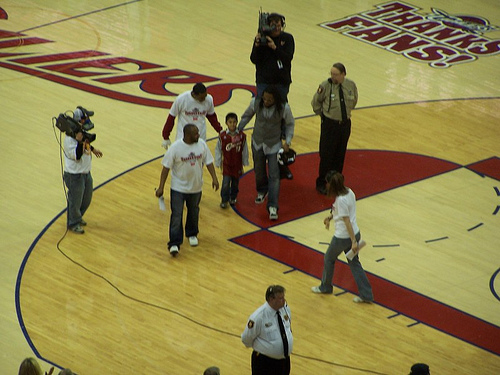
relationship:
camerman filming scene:
[249, 6, 299, 180] [146, 6, 388, 306]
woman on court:
[310, 168, 377, 305] [6, 4, 496, 367]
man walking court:
[155, 121, 221, 256] [6, 4, 496, 367]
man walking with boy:
[159, 82, 226, 152] [212, 113, 251, 210]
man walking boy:
[159, 82, 226, 152] [212, 113, 251, 210]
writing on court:
[316, 0, 499, 72] [6, 4, 496, 367]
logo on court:
[0, 6, 259, 112] [6, 4, 496, 367]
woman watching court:
[11, 353, 61, 375] [6, 4, 496, 367]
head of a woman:
[17, 357, 43, 375] [11, 353, 61, 375]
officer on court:
[311, 61, 359, 195] [6, 4, 496, 367]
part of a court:
[95, 17, 231, 56] [6, 4, 496, 367]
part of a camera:
[260, 19, 268, 32] [256, 8, 276, 46]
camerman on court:
[249, 6, 299, 180] [6, 4, 496, 367]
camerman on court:
[50, 104, 105, 238] [6, 4, 496, 367]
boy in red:
[212, 113, 251, 210] [221, 132, 244, 175]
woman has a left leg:
[310, 168, 377, 305] [311, 243, 342, 297]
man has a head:
[155, 121, 221, 256] [183, 121, 202, 145]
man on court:
[155, 121, 221, 256] [6, 4, 496, 367]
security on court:
[239, 283, 299, 375] [6, 4, 496, 367]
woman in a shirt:
[310, 168, 377, 305] [330, 188, 363, 240]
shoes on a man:
[160, 233, 200, 256] [155, 121, 221, 256]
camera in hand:
[256, 8, 276, 46] [264, 35, 279, 53]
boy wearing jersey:
[212, 113, 251, 210] [221, 132, 244, 175]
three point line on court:
[13, 7, 116, 50] [6, 4, 496, 367]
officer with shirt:
[311, 61, 359, 195] [310, 78, 359, 122]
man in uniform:
[311, 61, 359, 195] [313, 79, 355, 182]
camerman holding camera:
[249, 6, 299, 180] [256, 8, 276, 46]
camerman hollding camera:
[50, 104, 105, 238] [54, 111, 97, 145]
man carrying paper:
[155, 121, 221, 256] [153, 185, 167, 212]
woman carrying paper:
[310, 168, 377, 305] [343, 241, 368, 263]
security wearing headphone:
[239, 283, 299, 375] [268, 286, 290, 311]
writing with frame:
[316, 0, 499, 72] [344, 31, 364, 39]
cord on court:
[53, 216, 387, 374] [6, 4, 496, 367]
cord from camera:
[53, 216, 387, 374] [54, 111, 97, 145]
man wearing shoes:
[155, 121, 221, 256] [160, 233, 200, 256]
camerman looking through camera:
[249, 6, 299, 180] [256, 8, 276, 46]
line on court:
[289, 182, 452, 216] [6, 4, 496, 367]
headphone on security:
[268, 286, 290, 311] [239, 283, 299, 375]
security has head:
[239, 283, 299, 375] [264, 280, 289, 310]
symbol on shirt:
[182, 106, 207, 122] [159, 92, 224, 146]